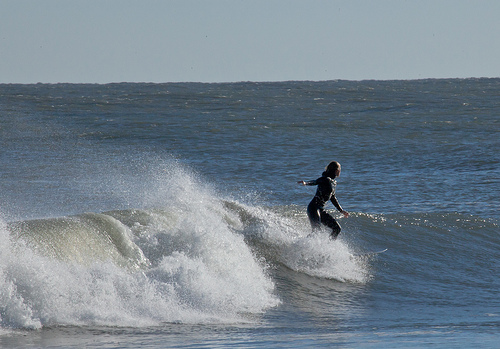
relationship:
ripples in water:
[148, 85, 357, 134] [3, 69, 498, 345]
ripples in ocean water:
[289, 203, 499, 230] [1, 82, 498, 347]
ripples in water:
[289, 203, 499, 230] [3, 69, 498, 345]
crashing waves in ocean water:
[4, 202, 271, 347] [1, 77, 499, 347]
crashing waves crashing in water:
[0, 192, 373, 348] [3, 69, 498, 345]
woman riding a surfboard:
[297, 161, 351, 244] [346, 237, 391, 259]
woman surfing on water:
[290, 160, 348, 256] [132, 262, 444, 321]